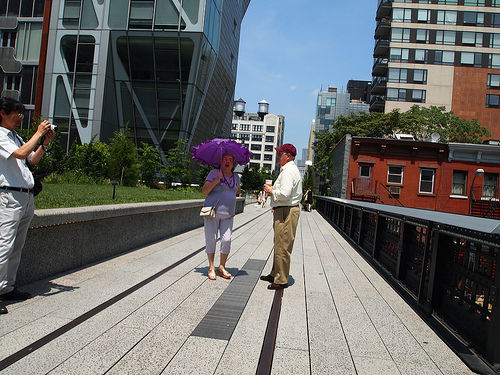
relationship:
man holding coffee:
[264, 143, 303, 290] [260, 176, 274, 190]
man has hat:
[264, 143, 303, 290] [267, 140, 300, 160]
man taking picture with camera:
[1, 94, 53, 314] [40, 117, 59, 136]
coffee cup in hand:
[266, 177, 276, 187] [263, 183, 270, 191]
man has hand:
[264, 143, 303, 290] [263, 183, 270, 191]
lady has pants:
[200, 152, 240, 280] [197, 209, 242, 265]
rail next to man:
[312, 193, 500, 375] [264, 143, 303, 290]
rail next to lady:
[312, 193, 500, 375] [200, 152, 240, 280]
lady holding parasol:
[200, 152, 240, 280] [190, 138, 253, 183]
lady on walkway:
[200, 152, 240, 280] [17, 159, 477, 371]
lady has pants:
[200, 152, 240, 280] [203, 213, 233, 254]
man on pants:
[264, 143, 303, 290] [269, 203, 300, 285]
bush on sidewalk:
[54, 133, 89, 173] [0, 193, 478, 374]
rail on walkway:
[331, 193, 498, 293] [299, 206, 382, 332]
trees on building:
[310, 103, 490, 196] [366, 3, 497, 144]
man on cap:
[264, 143, 303, 290] [272, 142, 302, 159]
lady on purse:
[200, 153, 240, 280] [200, 207, 213, 219]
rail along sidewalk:
[312, 193, 500, 375] [30, 129, 470, 372]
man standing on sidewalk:
[261, 131, 305, 297] [0, 193, 478, 374]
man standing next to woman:
[261, 131, 305, 297] [191, 137, 239, 276]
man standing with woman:
[264, 143, 303, 290] [202, 155, 239, 248]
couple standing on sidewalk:
[191, 135, 308, 300] [0, 193, 478, 374]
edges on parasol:
[190, 137, 252, 169] [190, 138, 253, 183]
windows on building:
[367, 3, 497, 122] [366, 3, 497, 144]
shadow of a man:
[25, 270, 75, 304] [264, 143, 303, 290]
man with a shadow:
[264, 143, 303, 290] [25, 270, 75, 304]